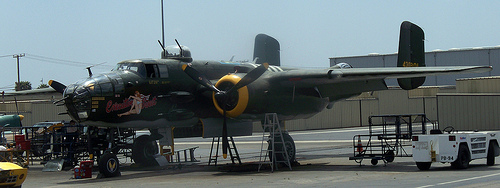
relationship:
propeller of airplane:
[177, 60, 270, 160] [46, 33, 492, 178]